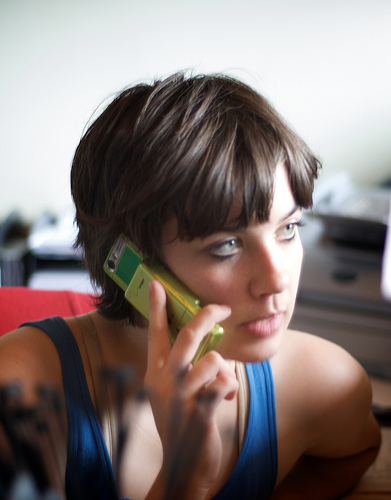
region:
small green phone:
[98, 234, 234, 350]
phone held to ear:
[109, 227, 216, 349]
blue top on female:
[36, 371, 277, 498]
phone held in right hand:
[96, 254, 236, 475]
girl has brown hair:
[85, 126, 300, 194]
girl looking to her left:
[100, 143, 309, 350]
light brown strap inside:
[234, 363, 252, 446]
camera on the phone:
[105, 258, 129, 280]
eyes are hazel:
[280, 223, 302, 234]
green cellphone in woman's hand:
[90, 245, 229, 343]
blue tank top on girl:
[30, 310, 291, 497]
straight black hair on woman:
[92, 67, 313, 224]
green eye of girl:
[221, 236, 240, 254]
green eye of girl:
[281, 220, 295, 233]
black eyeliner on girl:
[207, 232, 242, 263]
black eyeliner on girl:
[273, 222, 295, 242]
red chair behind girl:
[1, 288, 97, 325]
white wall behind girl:
[6, 6, 380, 217]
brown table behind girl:
[290, 232, 388, 342]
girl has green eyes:
[213, 220, 299, 254]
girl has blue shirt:
[60, 355, 285, 497]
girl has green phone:
[100, 241, 267, 378]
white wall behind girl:
[62, 16, 188, 104]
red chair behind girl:
[2, 274, 86, 328]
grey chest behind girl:
[310, 218, 384, 358]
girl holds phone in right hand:
[97, 213, 218, 440]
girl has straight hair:
[86, 84, 290, 232]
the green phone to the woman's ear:
[103, 232, 222, 366]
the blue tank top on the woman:
[16, 315, 278, 499]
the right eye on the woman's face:
[206, 237, 243, 256]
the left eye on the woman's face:
[273, 222, 294, 239]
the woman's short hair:
[70, 70, 320, 326]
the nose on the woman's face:
[248, 236, 285, 298]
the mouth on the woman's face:
[237, 309, 286, 336]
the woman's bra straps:
[75, 314, 250, 479]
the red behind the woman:
[0, 286, 111, 335]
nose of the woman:
[249, 249, 283, 296]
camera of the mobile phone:
[106, 258, 117, 273]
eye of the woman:
[275, 221, 300, 242]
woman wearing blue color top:
[61, 350, 88, 493]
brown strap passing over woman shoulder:
[80, 315, 104, 352]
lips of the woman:
[244, 311, 287, 336]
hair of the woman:
[104, 87, 223, 194]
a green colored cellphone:
[101, 234, 218, 364]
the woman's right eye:
[201, 238, 242, 259]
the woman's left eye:
[275, 221, 301, 239]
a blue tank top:
[17, 315, 281, 498]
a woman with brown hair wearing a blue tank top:
[0, 67, 381, 497]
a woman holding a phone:
[86, 243, 232, 360]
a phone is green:
[80, 237, 219, 374]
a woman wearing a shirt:
[76, 282, 278, 498]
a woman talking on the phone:
[71, 214, 310, 411]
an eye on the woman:
[207, 235, 246, 264]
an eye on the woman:
[276, 214, 304, 247]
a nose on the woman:
[243, 240, 291, 301]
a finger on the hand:
[206, 376, 238, 401]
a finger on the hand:
[178, 301, 231, 363]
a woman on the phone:
[84, 224, 191, 362]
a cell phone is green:
[84, 236, 233, 376]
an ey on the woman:
[189, 227, 230, 257]